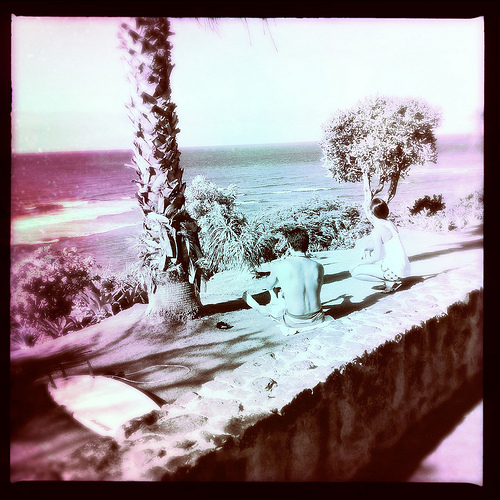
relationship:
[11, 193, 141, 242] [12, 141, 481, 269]
waves in ocean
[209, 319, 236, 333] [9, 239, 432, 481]
sandal on ground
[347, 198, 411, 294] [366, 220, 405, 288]
girl in suit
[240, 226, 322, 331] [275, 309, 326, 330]
boy in shorts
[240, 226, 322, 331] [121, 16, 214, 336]
boy near tree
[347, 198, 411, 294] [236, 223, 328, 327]
girl beside man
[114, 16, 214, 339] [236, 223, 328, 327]
palm tree near man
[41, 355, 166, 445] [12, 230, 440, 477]
surfboad on sand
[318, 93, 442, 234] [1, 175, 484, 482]
tree near beach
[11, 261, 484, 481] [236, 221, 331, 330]
wall behind person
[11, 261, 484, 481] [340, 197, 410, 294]
wall behind person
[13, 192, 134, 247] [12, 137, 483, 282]
water in ocean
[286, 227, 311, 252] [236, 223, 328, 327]
hair on man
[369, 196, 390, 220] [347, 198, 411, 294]
hair on girl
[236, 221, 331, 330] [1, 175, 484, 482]
person on beach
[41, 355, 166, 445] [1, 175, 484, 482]
surfboad on beach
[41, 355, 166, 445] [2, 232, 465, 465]
surfboad on sand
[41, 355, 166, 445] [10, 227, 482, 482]
surfboad on sand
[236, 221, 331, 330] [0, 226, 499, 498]
person on beach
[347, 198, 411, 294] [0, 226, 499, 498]
girl on beach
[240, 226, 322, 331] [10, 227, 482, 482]
boy sitting on sand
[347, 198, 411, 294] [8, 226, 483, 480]
girl squatting on ground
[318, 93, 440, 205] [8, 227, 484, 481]
tree on beach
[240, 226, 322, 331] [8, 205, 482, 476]
boy on beach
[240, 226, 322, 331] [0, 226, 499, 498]
boy on beach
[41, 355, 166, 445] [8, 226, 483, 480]
surfboad on ground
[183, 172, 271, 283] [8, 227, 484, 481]
tree by beach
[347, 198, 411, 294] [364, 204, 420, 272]
girl with top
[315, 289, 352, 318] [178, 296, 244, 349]
sunglasses on ground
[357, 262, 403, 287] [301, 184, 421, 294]
flip-flops on woman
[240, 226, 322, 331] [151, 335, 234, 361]
boy sitting ground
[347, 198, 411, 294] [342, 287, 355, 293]
girl kneeling ground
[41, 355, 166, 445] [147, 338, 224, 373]
surfboad on ground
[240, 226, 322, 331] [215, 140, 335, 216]
boy sitting water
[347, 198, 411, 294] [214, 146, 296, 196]
girl sitting water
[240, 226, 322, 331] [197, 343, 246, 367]
boy on ground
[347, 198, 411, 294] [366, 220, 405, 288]
girl wearing suit